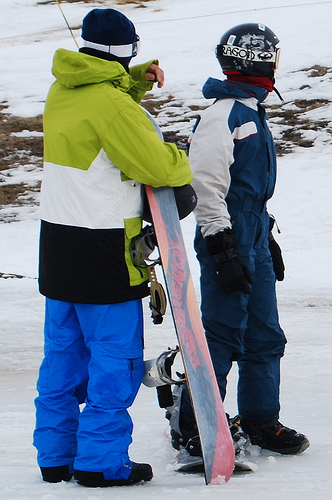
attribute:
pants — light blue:
[32, 295, 143, 479]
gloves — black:
[205, 230, 252, 296]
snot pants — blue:
[33, 298, 148, 472]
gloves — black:
[200, 227, 254, 295]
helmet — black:
[212, 21, 282, 78]